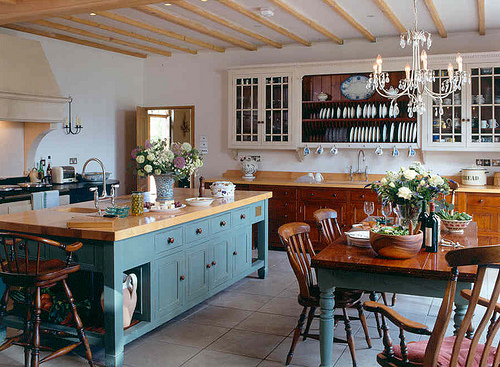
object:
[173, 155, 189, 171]
flower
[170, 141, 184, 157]
flower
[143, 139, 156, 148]
flower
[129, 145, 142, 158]
flower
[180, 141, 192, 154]
flower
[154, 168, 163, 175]
flower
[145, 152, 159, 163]
flower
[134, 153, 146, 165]
flower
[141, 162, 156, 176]
flower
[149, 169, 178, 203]
vase